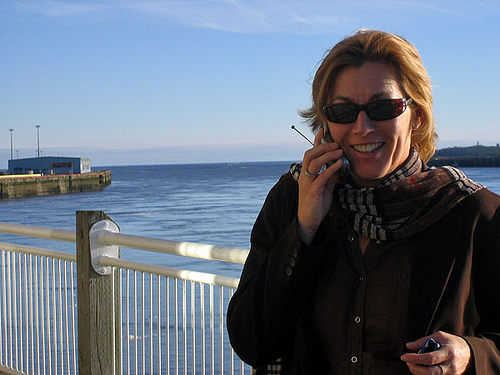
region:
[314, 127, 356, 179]
A cell phone in the woman's hand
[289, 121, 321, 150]
A small antenna on the cell phone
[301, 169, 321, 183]
A wedding band on the woman's finger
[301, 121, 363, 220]
The woman is holding a cell phone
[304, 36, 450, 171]
The woman has shoulder length hair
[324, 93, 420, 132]
Sunglasses on the woman's face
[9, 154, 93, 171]
A white building on the pier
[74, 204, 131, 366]
A short wooden pole by the woman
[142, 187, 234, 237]
The water looks calm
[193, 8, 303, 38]
A thin, wispy white cloud in the blue sky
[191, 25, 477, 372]
the woman on the cellphone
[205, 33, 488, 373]
the woman is smiling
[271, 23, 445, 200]
the woman wearing sunglasses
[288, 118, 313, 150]
the antenna of the cellphone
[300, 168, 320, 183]
the ring on the finger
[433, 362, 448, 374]
the ring on the finger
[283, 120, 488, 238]
the woman wearing a plaid scarf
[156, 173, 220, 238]
the water is calm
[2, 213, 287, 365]
the fence behind the woman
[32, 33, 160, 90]
the sky is blue and clear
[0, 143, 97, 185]
building at end of pier in the ocean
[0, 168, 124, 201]
pier jutting into the ocean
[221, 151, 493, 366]
dark brown sweater and scarf with white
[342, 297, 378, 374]
white buttons on front of sweater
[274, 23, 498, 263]
woman talking on a cell phone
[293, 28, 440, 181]
woman with smile and dark glasses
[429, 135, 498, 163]
hills and sky in the background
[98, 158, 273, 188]
dark blue ocean water with waves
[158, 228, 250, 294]
sunlight reflecting off two rails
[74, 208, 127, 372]
fence post holding rails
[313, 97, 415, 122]
dark black sunglasses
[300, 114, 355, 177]
a flip cellphone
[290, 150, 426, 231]
a woman's black and gray scarf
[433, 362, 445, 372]
a woman's silver ring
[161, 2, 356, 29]
a small white cloud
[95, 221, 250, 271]
a long white pole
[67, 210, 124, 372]
a tall gray pole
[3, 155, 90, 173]
a long gray building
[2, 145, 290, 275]
a large body of blue water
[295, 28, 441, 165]
a woman's blonde hair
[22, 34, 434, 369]
picture taken outside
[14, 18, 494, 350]
picture taken during the day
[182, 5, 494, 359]
A woman on her cell phone.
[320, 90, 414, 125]
the woman is wearing sun glasses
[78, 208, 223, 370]
railing behind the woman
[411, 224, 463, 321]
the woman is wearing a brown sweater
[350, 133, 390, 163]
the woman is smiling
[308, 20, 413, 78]
the woman has short hair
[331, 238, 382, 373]
buttons on the sweater